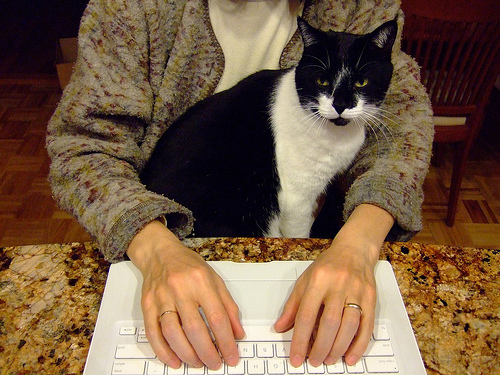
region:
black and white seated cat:
[143, 18, 387, 235]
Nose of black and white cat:
[331, 96, 350, 108]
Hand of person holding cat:
[274, 240, 378, 367]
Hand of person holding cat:
[139, 260, 247, 370]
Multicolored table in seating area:
[427, 269, 484, 342]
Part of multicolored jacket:
[104, 40, 153, 100]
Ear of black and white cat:
[374, 17, 399, 48]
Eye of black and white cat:
[350, 69, 373, 87]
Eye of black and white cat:
[315, 71, 330, 87]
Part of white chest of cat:
[293, 131, 319, 185]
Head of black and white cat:
[298, 11, 393, 126]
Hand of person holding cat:
[143, 259, 249, 369]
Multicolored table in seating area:
[8, 265, 66, 325]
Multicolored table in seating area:
[416, 249, 492, 319]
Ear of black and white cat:
[295, 12, 325, 48]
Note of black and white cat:
[333, 89, 351, 105]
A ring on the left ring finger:
[346, 300, 361, 314]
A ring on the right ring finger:
[157, 306, 176, 320]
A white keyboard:
[88, 263, 410, 373]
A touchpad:
[210, 270, 304, 318]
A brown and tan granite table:
[2, 238, 497, 373]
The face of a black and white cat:
[298, 13, 396, 128]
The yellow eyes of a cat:
[311, 70, 374, 91]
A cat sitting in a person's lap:
[142, 15, 399, 240]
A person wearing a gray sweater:
[50, 0, 438, 245]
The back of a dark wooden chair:
[400, 1, 499, 224]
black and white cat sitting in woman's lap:
[141, 20, 399, 240]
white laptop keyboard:
[82, 257, 427, 374]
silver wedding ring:
[344, 303, 363, 310]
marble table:
[0, 237, 499, 374]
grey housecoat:
[44, 0, 434, 259]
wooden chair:
[393, 0, 496, 225]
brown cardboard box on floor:
[52, 36, 77, 89]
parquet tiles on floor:
[0, 75, 497, 250]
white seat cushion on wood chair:
[420, 66, 462, 124]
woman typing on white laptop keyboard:
[46, 1, 433, 373]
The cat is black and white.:
[138, 14, 400, 237]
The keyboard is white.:
[77, 258, 428, 373]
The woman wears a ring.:
[343, 301, 364, 316]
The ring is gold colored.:
[343, 301, 363, 315]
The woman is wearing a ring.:
[158, 307, 180, 317]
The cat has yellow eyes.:
[313, 73, 371, 88]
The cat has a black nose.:
[331, 100, 348, 115]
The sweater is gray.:
[43, 0, 436, 244]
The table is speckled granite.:
[1, 235, 499, 373]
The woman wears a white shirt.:
[208, 0, 306, 91]